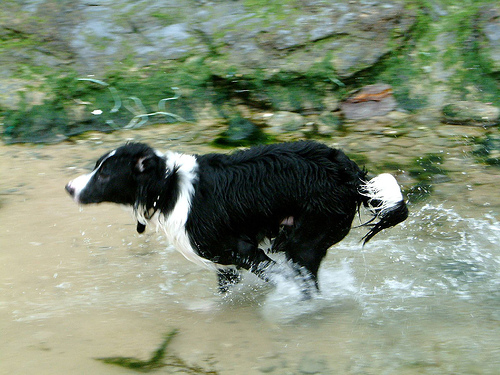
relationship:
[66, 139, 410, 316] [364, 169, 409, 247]
dog has a tail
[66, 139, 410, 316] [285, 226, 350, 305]
dog has a leg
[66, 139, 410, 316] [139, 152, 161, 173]
dog has an ear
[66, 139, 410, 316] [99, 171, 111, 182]
dog has an eye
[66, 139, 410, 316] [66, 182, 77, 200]
dog has a nose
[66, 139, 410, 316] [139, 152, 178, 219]
dog has a neck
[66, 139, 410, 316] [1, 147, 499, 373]
dog in water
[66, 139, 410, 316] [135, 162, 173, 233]
dog has a collar